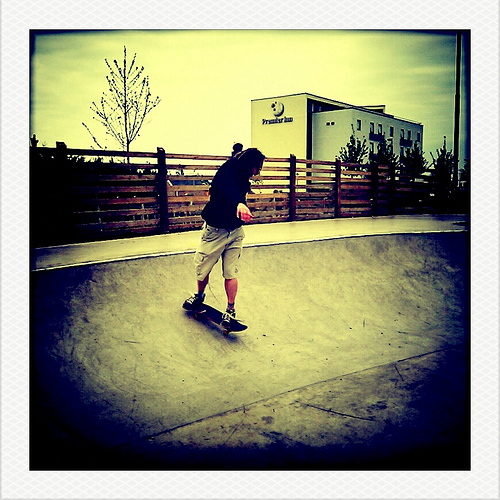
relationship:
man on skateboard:
[85, 117, 367, 356] [163, 285, 258, 347]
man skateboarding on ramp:
[182, 147, 264, 318] [28, 228, 468, 468]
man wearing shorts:
[182, 147, 264, 318] [183, 216, 258, 286]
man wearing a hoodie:
[182, 147, 264, 318] [201, 148, 265, 230]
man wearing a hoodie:
[182, 147, 264, 318] [200, 158, 250, 232]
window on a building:
[353, 117, 361, 131] [250, 92, 422, 204]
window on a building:
[368, 121, 378, 135] [250, 92, 422, 204]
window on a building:
[379, 124, 386, 135] [250, 92, 422, 204]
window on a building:
[407, 130, 412, 137] [250, 92, 422, 204]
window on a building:
[414, 131, 422, 143] [250, 92, 422, 204]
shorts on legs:
[196, 222, 243, 279] [191, 224, 242, 313]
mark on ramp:
[297, 392, 382, 430] [28, 228, 468, 468]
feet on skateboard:
[181, 289, 236, 326] [181, 296, 246, 338]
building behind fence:
[250, 96, 421, 216] [31, 131, 470, 239]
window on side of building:
[357, 119, 362, 130] [251, 92, 424, 210]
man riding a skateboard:
[182, 147, 264, 318] [195, 305, 249, 337]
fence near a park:
[31, 131, 470, 239] [30, 213, 472, 473]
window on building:
[367, 120, 374, 134] [250, 92, 422, 204]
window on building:
[355, 116, 362, 128] [250, 92, 422, 204]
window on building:
[379, 123, 384, 134] [250, 92, 422, 204]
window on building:
[390, 126, 394, 136] [250, 92, 422, 204]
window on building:
[398, 127, 406, 141] [250, 92, 422, 204]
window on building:
[370, 123, 375, 134] [250, 92, 422, 204]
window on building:
[354, 117, 363, 128] [250, 92, 422, 204]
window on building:
[390, 124, 394, 136] [250, 92, 422, 204]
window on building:
[408, 130, 412, 140] [250, 92, 422, 204]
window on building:
[416, 129, 421, 142] [250, 92, 422, 204]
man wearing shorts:
[182, 147, 264, 318] [190, 220, 247, 283]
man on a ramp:
[182, 147, 264, 318] [27, 208, 472, 473]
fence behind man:
[31, 131, 470, 239] [180, 144, 268, 353]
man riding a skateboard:
[182, 147, 264, 318] [179, 291, 250, 340]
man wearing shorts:
[182, 147, 264, 318] [179, 224, 245, 285]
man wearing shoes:
[182, 147, 264, 318] [177, 293, 239, 330]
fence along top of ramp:
[31, 131, 470, 239] [28, 228, 468, 468]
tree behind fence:
[335, 139, 365, 178] [264, 157, 456, 217]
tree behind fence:
[366, 130, 396, 178] [264, 157, 456, 217]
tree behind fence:
[396, 132, 421, 181] [264, 157, 456, 217]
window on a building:
[378, 124, 383, 134] [307, 104, 429, 186]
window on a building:
[354, 119, 365, 134] [243, 88, 428, 175]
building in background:
[251, 92, 424, 210] [75, 127, 438, 207]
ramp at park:
[28, 228, 468, 468] [30, 213, 472, 473]